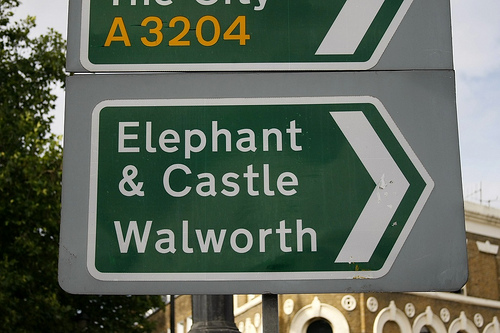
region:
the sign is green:
[98, 103, 385, 280]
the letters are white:
[108, 109, 323, 269]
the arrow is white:
[335, 102, 417, 285]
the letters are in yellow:
[98, 16, 290, 64]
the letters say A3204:
[98, 8, 310, 78]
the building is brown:
[208, 203, 493, 331]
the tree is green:
[0, 0, 160, 330]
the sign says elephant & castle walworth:
[119, 119, 381, 264]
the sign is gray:
[70, 0, 472, 313]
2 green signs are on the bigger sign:
[86, 2, 430, 324]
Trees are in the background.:
[1, 35, 64, 327]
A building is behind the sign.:
[360, 169, 498, 329]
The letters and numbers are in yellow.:
[96, 12, 268, 54]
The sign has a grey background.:
[53, 74, 464, 299]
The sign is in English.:
[73, 84, 450, 286]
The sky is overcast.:
[446, 12, 498, 201]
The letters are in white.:
[103, 118, 328, 265]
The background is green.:
[93, 97, 431, 281]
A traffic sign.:
[74, 83, 456, 287]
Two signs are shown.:
[61, 1, 471, 301]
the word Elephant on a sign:
[117, 120, 304, 155]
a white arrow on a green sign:
[326, 102, 411, 272]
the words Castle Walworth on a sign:
[120, 167, 320, 259]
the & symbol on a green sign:
[116, 160, 151, 201]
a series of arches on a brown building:
[296, 292, 491, 330]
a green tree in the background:
[2, 227, 59, 324]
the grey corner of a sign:
[417, 235, 467, 288]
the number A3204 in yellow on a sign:
[106, 14, 254, 53]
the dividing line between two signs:
[70, 60, 458, 82]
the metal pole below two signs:
[181, 294, 243, 329]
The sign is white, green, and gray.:
[46, 65, 471, 298]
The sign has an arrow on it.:
[305, 91, 435, 268]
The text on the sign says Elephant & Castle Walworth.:
[113, 115, 334, 263]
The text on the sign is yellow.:
[95, 13, 276, 53]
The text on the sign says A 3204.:
[92, 11, 284, 57]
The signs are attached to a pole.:
[57, 2, 459, 330]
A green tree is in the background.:
[5, 36, 55, 313]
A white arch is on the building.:
[280, 297, 351, 330]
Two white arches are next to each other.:
[372, 296, 447, 329]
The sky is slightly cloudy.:
[464, 1, 499, 130]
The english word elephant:
[118, 113, 305, 165]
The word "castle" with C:
[156, 163, 313, 211]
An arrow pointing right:
[323, 101, 450, 282]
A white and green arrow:
[334, 91, 430, 271]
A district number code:
[97, 18, 256, 65]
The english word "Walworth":
[91, 207, 329, 269]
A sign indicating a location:
[49, 61, 455, 315]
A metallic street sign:
[56, 56, 454, 296]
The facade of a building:
[304, 297, 451, 329]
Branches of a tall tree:
[16, 21, 48, 201]